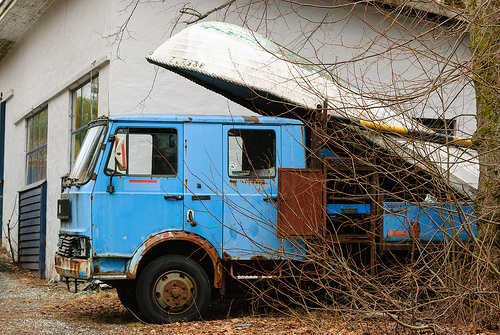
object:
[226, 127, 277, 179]
window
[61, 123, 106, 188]
window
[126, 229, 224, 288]
rust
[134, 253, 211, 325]
wheel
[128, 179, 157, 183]
red stripe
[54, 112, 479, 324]
blue truck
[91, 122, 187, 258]
blue door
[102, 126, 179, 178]
window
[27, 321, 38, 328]
gravel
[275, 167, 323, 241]
rust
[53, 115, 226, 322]
cab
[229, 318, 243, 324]
leaves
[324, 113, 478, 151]
pole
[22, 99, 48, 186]
window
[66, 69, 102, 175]
window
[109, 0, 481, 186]
walls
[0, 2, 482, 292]
building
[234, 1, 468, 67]
branches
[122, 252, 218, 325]
tire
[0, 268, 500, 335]
ground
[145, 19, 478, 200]
boat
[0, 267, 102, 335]
driveway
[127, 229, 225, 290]
wheel well